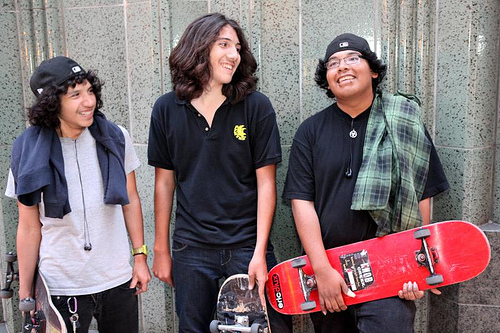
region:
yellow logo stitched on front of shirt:
[225, 113, 258, 153]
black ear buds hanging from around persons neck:
[65, 131, 109, 261]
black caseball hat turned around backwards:
[324, 19, 384, 91]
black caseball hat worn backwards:
[13, 47, 114, 99]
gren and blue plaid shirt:
[361, 86, 433, 256]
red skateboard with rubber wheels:
[260, 223, 498, 300]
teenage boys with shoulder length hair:
[165, 13, 267, 110]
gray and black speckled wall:
[265, 9, 326, 103]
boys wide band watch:
[117, 236, 154, 262]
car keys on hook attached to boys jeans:
[52, 289, 89, 332]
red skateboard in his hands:
[271, 213, 491, 322]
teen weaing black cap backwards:
[319, 31, 381, 84]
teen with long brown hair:
[179, 26, 272, 114]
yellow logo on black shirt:
[230, 115, 247, 144]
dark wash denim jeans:
[166, 236, 284, 328]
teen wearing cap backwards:
[25, 59, 100, 134]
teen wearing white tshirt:
[11, 128, 141, 292]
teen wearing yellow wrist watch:
[129, 245, 148, 266]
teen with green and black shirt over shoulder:
[356, 96, 433, 234]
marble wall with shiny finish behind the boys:
[10, 3, 492, 320]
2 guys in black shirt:
[124, 5, 466, 331]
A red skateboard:
[269, 220, 493, 312]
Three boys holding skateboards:
[12, 10, 438, 318]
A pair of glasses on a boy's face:
[322, 53, 367, 68]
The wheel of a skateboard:
[411, 225, 431, 241]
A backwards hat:
[22, 55, 89, 97]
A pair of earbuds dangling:
[67, 134, 98, 254]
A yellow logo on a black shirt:
[228, 117, 248, 144]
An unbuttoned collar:
[191, 96, 226, 139]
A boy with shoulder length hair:
[168, 13, 260, 102]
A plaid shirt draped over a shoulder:
[356, 88, 442, 227]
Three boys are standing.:
[21, 17, 454, 230]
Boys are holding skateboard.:
[10, 246, 461, 331]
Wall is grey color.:
[48, 12, 168, 59]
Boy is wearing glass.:
[326, 43, 366, 73]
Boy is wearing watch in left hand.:
[130, 237, 145, 257]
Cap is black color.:
[20, 35, 376, 86]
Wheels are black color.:
[1, 237, 461, 329]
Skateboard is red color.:
[275, 242, 478, 297]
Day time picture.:
[27, 42, 494, 319]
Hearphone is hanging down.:
[83, 208, 100, 254]